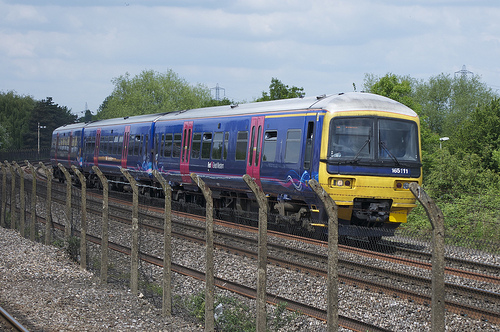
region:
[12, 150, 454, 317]
bent poles supporting wire fencing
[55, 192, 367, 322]
tracks on the side of train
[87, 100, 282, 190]
red doors on blue train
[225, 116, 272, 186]
oval windows on doors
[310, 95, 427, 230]
front of train painted yellow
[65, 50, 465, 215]
trees growing behind train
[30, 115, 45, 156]
pole with sign behind train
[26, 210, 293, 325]
plants growing along fence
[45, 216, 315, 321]
grey gravel between the rails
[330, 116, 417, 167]
double windows across front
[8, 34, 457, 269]
commuter train on tracks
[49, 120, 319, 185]
blue cars with red doors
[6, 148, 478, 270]
two sets railroad tracks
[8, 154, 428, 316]
steel posts down fence line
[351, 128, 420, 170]
windshield wipers on train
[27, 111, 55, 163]
signal pole beside tracks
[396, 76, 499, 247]
trees behind train tracks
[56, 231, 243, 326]
weeds growing along fence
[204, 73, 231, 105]
tall tower behind trees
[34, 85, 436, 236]
Passenger train on rails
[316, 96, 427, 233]
Front of train is yellow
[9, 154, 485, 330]
Fence close to rails of train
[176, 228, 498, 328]
Rails of train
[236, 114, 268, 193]
Door of train is red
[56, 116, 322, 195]
Side of train is red and blue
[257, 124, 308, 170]
Window of train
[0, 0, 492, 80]
Sky is cloudy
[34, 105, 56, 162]
Pole on the background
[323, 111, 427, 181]
Big window in front of train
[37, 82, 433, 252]
Train of passenger is blue and yellow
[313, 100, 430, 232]
Yellow in front of train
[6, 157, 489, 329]
Fence next to rail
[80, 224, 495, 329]
Rail on the ground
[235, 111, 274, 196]
Double door of train is red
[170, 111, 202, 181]
Double door of train is red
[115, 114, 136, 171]
Double door of train is red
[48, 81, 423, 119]
Roof of train is grey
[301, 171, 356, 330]
Stick is wood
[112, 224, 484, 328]
Rails are filled with gravel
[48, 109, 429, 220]
the short passenger train going down the track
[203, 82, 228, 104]
the top of a power pole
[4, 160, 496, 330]
the fence next to the track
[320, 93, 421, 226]
the front end of the train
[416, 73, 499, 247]
some of the bushes next to the train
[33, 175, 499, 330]
a train track next to the train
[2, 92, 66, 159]
some more trees behind the train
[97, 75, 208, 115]
some more trees behind the train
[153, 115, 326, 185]
the windows of the train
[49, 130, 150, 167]
some more windows of the train